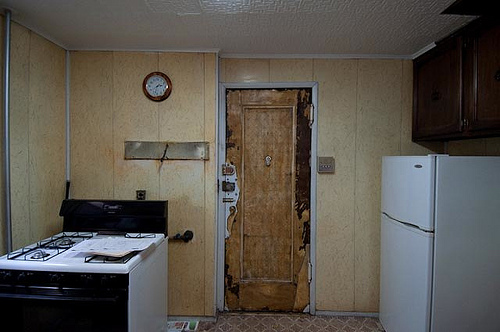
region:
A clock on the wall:
[130, 69, 179, 107]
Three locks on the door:
[207, 159, 244, 210]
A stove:
[13, 197, 183, 328]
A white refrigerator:
[365, 135, 496, 327]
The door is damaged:
[205, 60, 327, 325]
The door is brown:
[204, 65, 325, 320]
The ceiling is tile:
[232, 6, 382, 51]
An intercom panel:
[313, 151, 339, 177]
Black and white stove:
[9, 180, 180, 326]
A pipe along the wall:
[2, 8, 16, 248]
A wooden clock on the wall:
[135, 68, 184, 105]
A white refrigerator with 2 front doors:
[373, 150, 496, 327]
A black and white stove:
[0, 221, 188, 330]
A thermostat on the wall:
[315, 150, 338, 186]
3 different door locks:
[219, 150, 240, 228]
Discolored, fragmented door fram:
[287, 81, 320, 258]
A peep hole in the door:
[260, 150, 277, 171]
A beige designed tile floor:
[261, 313, 327, 330]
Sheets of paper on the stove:
[63, 226, 168, 266]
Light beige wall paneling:
[82, 89, 124, 176]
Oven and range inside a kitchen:
[0, 223, 175, 328]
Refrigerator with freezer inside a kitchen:
[361, 147, 497, 328]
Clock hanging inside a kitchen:
[133, 67, 176, 103]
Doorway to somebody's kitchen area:
[206, 73, 321, 324]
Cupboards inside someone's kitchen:
[405, 40, 496, 145]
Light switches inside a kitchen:
[312, 150, 337, 176]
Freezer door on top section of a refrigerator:
[375, 150, 442, 231]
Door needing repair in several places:
[223, 85, 310, 310]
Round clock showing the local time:
[128, 65, 181, 107]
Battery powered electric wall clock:
[131, 65, 177, 112]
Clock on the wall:
[140, 71, 174, 100]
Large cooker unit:
[3, 216, 176, 328]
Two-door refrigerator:
[374, 150, 495, 325]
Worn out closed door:
[210, 78, 325, 317]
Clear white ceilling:
[17, 24, 492, 62]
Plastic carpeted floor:
[201, 314, 387, 330]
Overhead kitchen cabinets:
[408, 62, 493, 143]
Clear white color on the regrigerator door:
[388, 165, 418, 207]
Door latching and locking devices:
[215, 156, 236, 206]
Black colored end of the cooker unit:
[8, 286, 119, 322]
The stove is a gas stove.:
[16, 181, 178, 326]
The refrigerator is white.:
[374, 143, 489, 326]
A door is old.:
[213, 85, 321, 320]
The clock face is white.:
[141, 69, 181, 111]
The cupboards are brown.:
[420, 57, 493, 121]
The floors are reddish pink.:
[246, 316, 298, 328]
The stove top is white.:
[36, 225, 168, 266]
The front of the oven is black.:
[7, 270, 128, 317]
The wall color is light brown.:
[88, 107, 124, 131]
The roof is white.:
[230, 20, 331, 45]